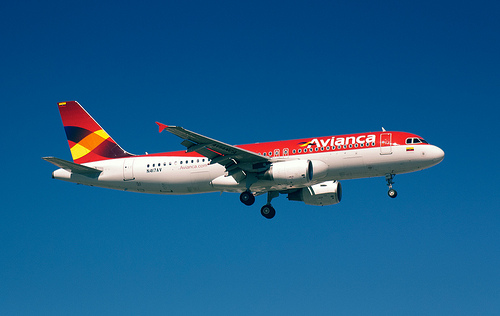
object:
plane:
[42, 100, 444, 219]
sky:
[1, 0, 497, 315]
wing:
[155, 121, 271, 184]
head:
[389, 131, 445, 175]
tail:
[56, 101, 136, 164]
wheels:
[240, 191, 256, 206]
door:
[380, 133, 392, 155]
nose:
[430, 143, 445, 166]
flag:
[406, 147, 414, 152]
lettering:
[307, 135, 376, 149]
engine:
[258, 159, 314, 185]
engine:
[287, 179, 342, 206]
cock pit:
[404, 131, 444, 173]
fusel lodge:
[50, 132, 445, 195]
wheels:
[388, 189, 398, 198]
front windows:
[406, 137, 428, 144]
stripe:
[64, 126, 135, 159]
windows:
[372, 143, 375, 146]